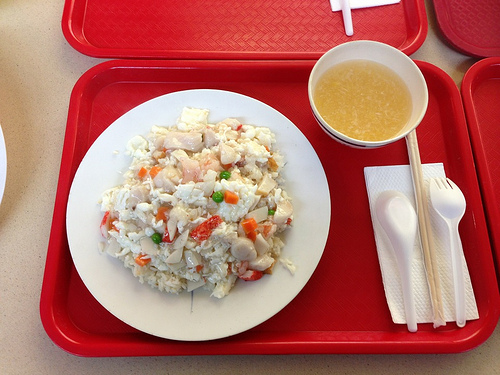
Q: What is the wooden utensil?
A: Chopsticks.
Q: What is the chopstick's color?
A: Brown.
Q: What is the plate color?
A: White.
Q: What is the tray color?
A: Red.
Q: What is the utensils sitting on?
A: Napkin.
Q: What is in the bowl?
A: Soup.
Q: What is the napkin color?
A: White.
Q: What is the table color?
A: White.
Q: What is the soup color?
A: Yellow.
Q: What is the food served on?
A: Red tray.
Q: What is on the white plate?
A: Fried rice.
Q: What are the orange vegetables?
A: Carrots.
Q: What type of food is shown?
A: Stir Fry.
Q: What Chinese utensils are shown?
A: Chopsticks.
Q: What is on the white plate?
A: Chicken fried rice.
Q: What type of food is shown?
A: Chinese.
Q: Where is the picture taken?
A: A restaurant.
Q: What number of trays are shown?
A: Four.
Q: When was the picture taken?
A: After cooking.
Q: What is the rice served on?
A: White plate.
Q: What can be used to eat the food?
A: Chopsticks.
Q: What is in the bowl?
A: Soup.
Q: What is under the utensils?
A: A napkin.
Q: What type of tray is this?
A: Cafeteria tray.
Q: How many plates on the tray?
A: One.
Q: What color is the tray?
A: Red.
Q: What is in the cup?
A: Soup.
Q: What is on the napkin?
A: Utensils.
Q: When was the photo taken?
A: Lunch time.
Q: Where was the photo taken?
A: A restaurant.